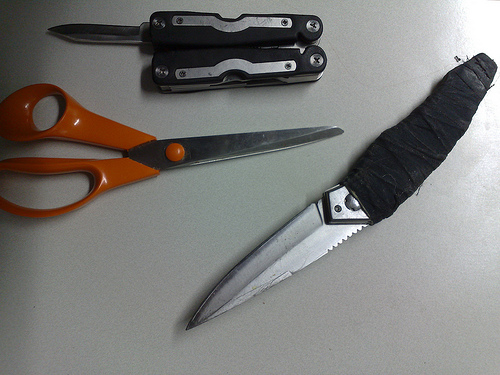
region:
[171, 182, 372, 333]
blade of a knife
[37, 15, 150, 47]
blade of a knife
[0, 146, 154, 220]
orange handle of scissors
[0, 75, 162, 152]
orange handle of scissors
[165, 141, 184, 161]
orange swivel on scissors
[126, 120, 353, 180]
blade of a pair of scissors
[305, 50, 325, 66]
screw on a multitool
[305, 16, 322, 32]
screw on a multitool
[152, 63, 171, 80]
screw on a multitool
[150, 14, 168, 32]
screw on a multitool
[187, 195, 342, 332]
blade of the knife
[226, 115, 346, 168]
blade of the scissors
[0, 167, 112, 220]
handle of the scissors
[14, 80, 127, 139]
handle of the scissors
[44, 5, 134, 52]
blade of the knife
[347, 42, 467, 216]
handle of the knife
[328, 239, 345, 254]
edge of the knife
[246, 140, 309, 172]
edge of the scissors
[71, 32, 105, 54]
edge of the knife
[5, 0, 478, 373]
assortment of sharp tools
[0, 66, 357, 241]
orange sharp scissors on table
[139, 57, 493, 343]
sharp knife with black handle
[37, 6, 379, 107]
sharp army knife with blade out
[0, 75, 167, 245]
orange handle on scissors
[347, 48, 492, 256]
black handle on scissors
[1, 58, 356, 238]
a pair of scissors on table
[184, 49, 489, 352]
a knife on the table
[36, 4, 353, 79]
an army knife on table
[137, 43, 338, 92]
folded black army knife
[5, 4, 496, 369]
plain gray surface under tools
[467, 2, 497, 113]
light reflection on surface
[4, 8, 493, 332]
three cutting tools on gray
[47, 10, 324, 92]
two jack knives side by side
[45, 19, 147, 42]
blade of jack knife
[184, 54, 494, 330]
knife with taped handle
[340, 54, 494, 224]
tape wrapped around handle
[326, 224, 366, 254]
serrated edge of knife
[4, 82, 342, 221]
scissor with orange handle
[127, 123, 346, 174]
metal blades on scissor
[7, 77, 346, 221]
plastic orange handled scissors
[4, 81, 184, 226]
shiny plastic orange scissor handles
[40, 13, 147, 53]
small utility knife blade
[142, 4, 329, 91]
black and silver handled utility knife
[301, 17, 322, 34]
small silver phillips head screw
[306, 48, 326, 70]
small silver phillips head screw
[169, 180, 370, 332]
shiny silver knife blade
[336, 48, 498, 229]
black wrapped knife handle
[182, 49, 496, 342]
large sharp metal knife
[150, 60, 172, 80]
small silver phillips head screw